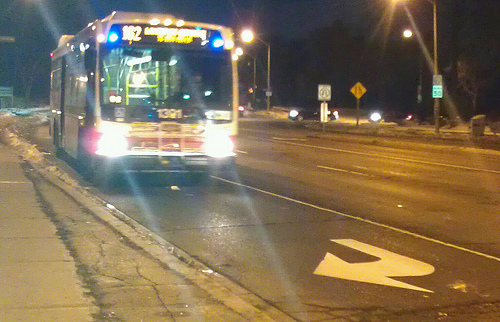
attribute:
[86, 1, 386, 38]
sky — black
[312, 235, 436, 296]
arrow — white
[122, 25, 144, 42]
number — 162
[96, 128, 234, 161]
lights — on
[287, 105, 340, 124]
car — black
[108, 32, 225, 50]
lights — blue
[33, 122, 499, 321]
street — gray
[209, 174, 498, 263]
line — white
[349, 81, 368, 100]
sign — yellow, lane merge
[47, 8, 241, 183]
bus — passenger, white, #1391, accessible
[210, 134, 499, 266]
lines — white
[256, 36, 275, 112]
pole — metal, grey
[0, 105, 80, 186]
snow — white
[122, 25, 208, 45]
sign — electric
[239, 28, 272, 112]
street light — large, tall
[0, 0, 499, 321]
scene — night time